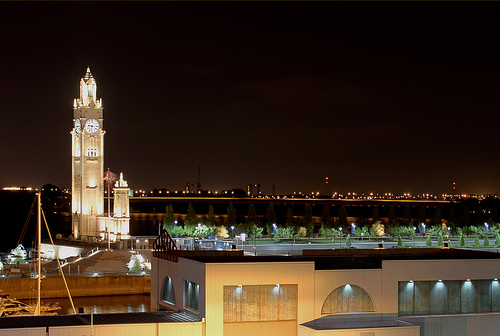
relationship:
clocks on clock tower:
[68, 119, 103, 134] [71, 67, 108, 240]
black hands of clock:
[88, 124, 95, 128] [84, 114, 98, 136]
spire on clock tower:
[81, 64, 95, 76] [71, 67, 108, 240]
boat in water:
[0, 292, 67, 320] [4, 291, 157, 310]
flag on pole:
[104, 166, 123, 186] [100, 165, 120, 247]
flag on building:
[104, 166, 123, 186] [56, 226, 145, 256]